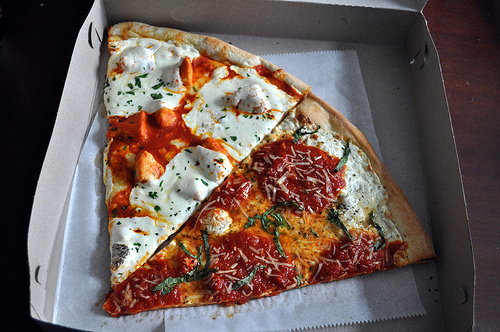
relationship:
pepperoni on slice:
[210, 235, 289, 294] [107, 96, 436, 318]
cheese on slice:
[118, 43, 190, 103] [104, 25, 298, 271]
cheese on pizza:
[269, 151, 319, 194] [115, 93, 443, 319]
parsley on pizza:
[255, 209, 291, 243] [102, 28, 430, 305]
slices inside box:
[111, 12, 310, 286] [12, 17, 482, 311]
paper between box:
[306, 53, 377, 90] [391, 28, 451, 158]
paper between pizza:
[306, 53, 377, 90] [104, 20, 411, 294]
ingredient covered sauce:
[192, 247, 283, 278] [285, 152, 325, 201]